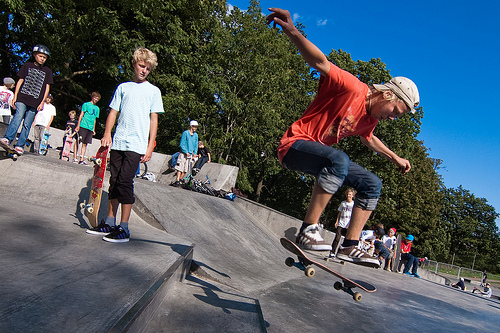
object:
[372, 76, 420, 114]
cap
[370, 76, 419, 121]
head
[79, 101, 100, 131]
shirt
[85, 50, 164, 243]
boy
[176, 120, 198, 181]
boy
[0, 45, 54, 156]
boy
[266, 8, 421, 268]
boy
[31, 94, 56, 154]
boy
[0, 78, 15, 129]
boy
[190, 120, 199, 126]
hat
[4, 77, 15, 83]
hat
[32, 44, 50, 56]
hat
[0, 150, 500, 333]
ground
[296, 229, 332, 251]
feet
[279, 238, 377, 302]
skateboard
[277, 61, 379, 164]
shirt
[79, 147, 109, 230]
skateboard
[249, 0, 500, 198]
sky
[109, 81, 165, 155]
blue shirt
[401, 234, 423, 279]
man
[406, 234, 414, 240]
cap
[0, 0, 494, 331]
skate park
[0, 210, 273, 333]
shadow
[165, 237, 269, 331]
steps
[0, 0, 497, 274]
green trees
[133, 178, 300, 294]
ramp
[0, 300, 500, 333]
concrete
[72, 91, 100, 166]
boy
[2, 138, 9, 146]
red shoes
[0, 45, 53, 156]
girl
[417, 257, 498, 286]
barricades